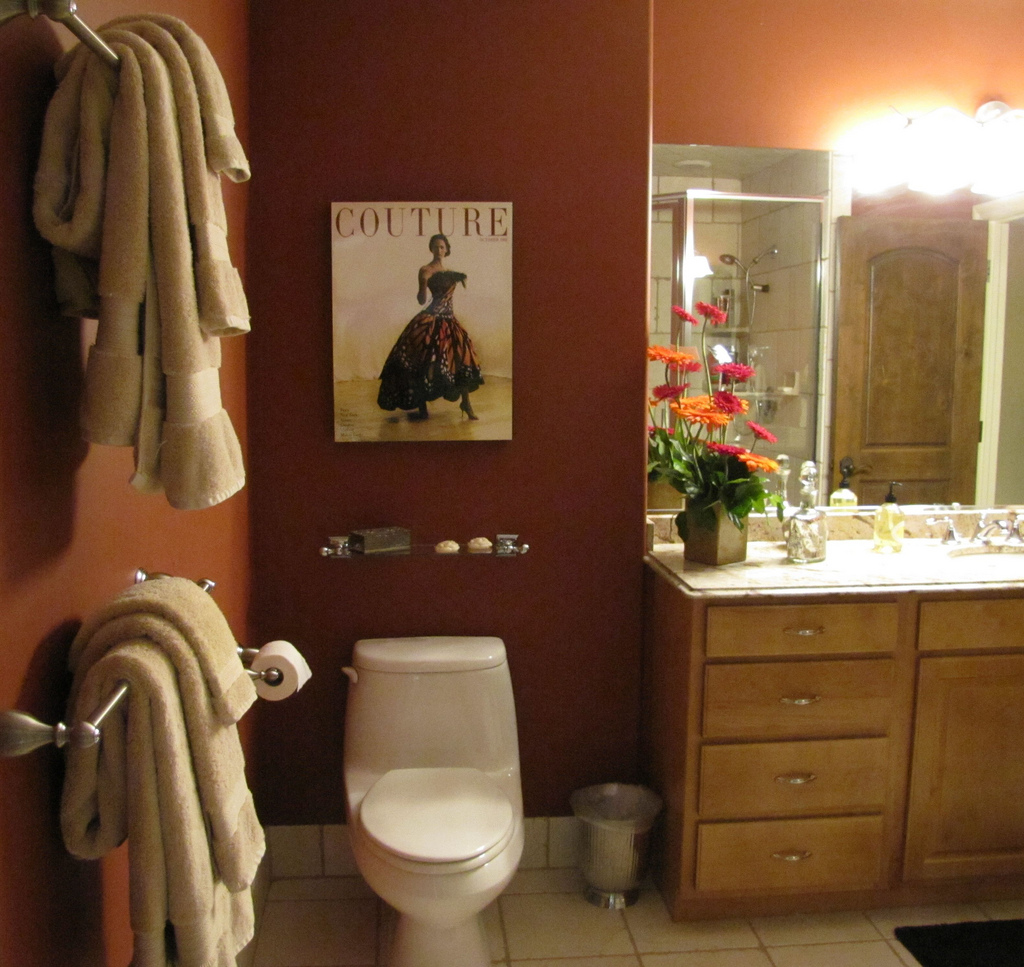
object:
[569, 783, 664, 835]
bag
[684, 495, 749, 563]
vase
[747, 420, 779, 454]
flowers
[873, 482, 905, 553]
lotion dispenser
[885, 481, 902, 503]
nozzle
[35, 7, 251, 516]
towel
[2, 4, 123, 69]
towel rack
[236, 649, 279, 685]
holder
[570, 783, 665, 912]
can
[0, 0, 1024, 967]
bathroom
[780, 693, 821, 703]
handle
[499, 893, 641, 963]
tiles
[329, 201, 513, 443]
picture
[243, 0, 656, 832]
wall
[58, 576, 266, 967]
towel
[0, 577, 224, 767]
rack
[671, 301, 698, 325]
flowers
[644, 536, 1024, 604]
counter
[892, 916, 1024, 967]
rug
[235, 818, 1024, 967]
floor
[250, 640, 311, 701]
dispenser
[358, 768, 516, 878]
toilet seat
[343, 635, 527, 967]
toilet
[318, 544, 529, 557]
shelf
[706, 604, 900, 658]
drawer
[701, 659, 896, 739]
drawer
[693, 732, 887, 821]
drawer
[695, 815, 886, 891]
drawer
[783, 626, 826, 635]
handle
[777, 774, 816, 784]
handle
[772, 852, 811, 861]
handle